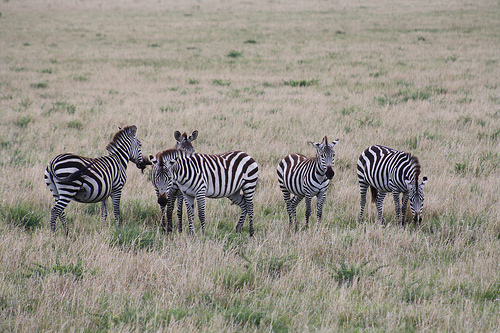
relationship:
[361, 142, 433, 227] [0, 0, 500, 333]
zebra standing ground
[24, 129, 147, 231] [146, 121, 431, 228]
zebra to left of four zebras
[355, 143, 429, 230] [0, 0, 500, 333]
zebra grazing in ground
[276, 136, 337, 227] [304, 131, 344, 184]
zebra has head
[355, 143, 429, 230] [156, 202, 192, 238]
zebra has leg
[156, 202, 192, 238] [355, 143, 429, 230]
leg touching zebra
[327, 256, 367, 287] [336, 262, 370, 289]
bush in grass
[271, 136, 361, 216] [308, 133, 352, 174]
zebra has head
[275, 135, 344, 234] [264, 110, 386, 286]
zebra looking at camera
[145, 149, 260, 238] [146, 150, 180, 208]
zebra has a head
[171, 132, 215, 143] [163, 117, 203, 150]
ears on head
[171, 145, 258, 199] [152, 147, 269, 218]
stripes on zebra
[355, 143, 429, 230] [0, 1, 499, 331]
zebra eating grass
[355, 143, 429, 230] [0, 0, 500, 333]
zebra on ground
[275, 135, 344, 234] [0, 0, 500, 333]
zebra on ground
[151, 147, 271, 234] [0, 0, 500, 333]
zebra on ground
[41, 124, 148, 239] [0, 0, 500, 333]
zebra on ground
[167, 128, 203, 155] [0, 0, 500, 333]
zebra on ground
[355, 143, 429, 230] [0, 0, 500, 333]
zebra grazing on ground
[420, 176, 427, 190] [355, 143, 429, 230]
ear of zebra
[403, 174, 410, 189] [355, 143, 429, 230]
ear of zebra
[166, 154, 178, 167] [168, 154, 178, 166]
stripes are on ear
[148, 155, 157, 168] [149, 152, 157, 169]
stripes are on ear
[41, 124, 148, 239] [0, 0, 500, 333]
zebra are resting in ground